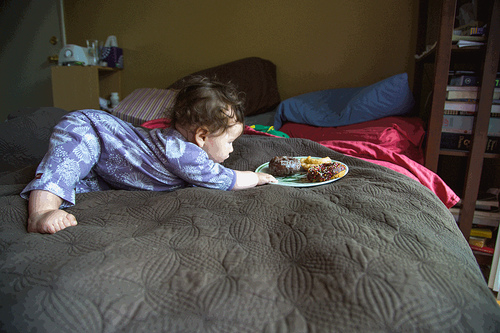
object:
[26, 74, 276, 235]
baby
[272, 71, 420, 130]
pillow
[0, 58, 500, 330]
bed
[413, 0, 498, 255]
book shelf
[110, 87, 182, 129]
pillow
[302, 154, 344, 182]
food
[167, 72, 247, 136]
hair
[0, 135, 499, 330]
bedspread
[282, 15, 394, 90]
wall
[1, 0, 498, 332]
picture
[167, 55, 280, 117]
pillow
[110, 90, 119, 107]
medicine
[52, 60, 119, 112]
shelf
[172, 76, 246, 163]
head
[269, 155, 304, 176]
donut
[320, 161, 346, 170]
sprinkles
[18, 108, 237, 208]
outfit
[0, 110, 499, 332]
blanket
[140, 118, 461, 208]
sheet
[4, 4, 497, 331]
bedroom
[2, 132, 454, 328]
design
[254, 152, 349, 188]
plate